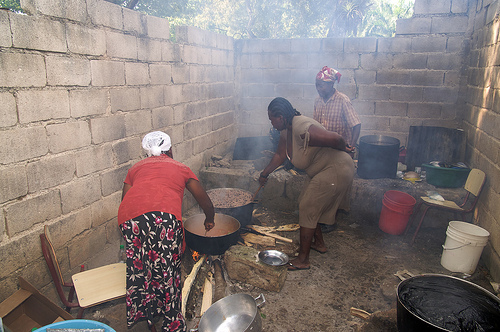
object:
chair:
[406, 166, 486, 248]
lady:
[115, 130, 215, 331]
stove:
[185, 244, 235, 266]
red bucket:
[377, 190, 417, 237]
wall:
[1, 0, 499, 307]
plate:
[259, 249, 291, 267]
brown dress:
[283, 114, 359, 229]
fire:
[189, 251, 210, 263]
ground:
[36, 200, 498, 330]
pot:
[396, 272, 500, 331]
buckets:
[438, 219, 489, 276]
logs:
[179, 255, 207, 321]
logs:
[243, 232, 276, 247]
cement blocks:
[15, 88, 72, 123]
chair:
[39, 224, 126, 318]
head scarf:
[316, 65, 341, 84]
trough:
[422, 161, 473, 188]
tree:
[223, 1, 382, 42]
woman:
[258, 97, 357, 271]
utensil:
[246, 176, 270, 204]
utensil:
[204, 227, 210, 236]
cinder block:
[65, 21, 108, 56]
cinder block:
[60, 173, 102, 215]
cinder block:
[90, 113, 125, 146]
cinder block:
[4, 186, 62, 237]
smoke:
[100, 0, 488, 239]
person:
[313, 66, 359, 158]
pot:
[181, 210, 242, 255]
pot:
[356, 133, 401, 179]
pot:
[201, 187, 254, 229]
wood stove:
[234, 200, 310, 248]